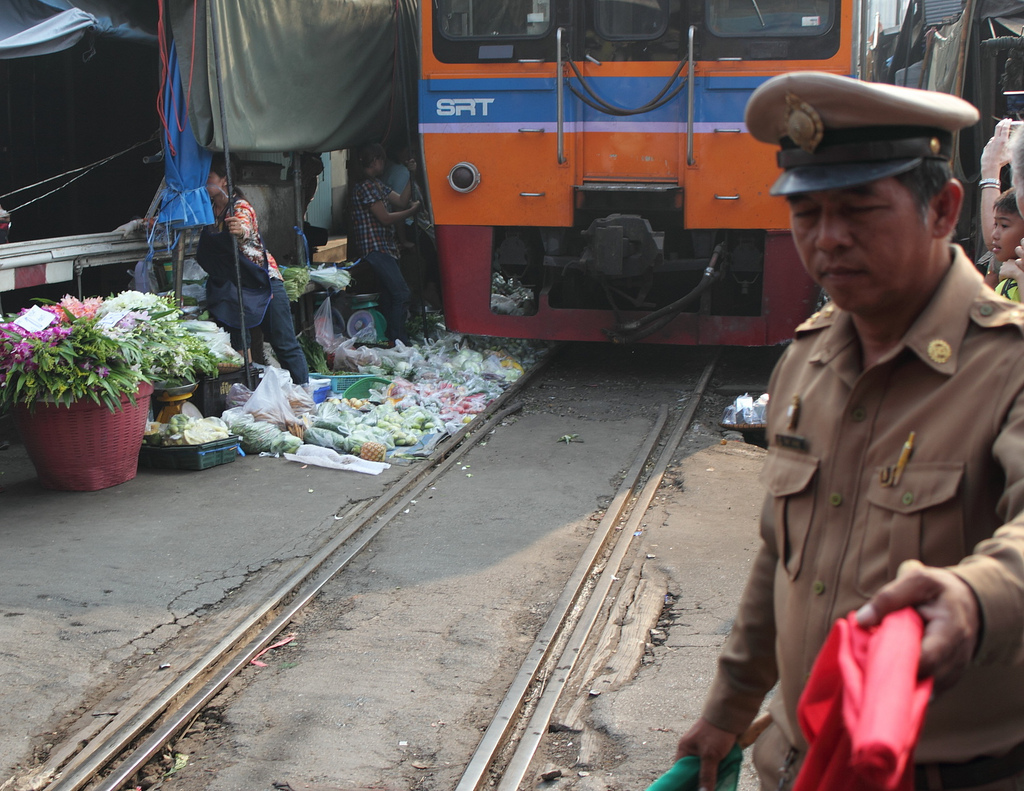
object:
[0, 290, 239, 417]
plant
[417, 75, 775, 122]
stripe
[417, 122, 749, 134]
stripe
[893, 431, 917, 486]
pen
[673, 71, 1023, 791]
man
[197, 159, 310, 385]
man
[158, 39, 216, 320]
blue umbrella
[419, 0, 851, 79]
window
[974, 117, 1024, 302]
child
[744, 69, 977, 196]
brown hat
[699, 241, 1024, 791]
cloth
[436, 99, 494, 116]
lettering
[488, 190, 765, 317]
bars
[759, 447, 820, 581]
pockets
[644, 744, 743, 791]
flag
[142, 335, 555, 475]
fruit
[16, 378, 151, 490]
flower basket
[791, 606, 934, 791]
flag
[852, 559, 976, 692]
man's hand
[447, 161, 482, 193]
light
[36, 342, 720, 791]
tracks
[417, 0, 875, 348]
train